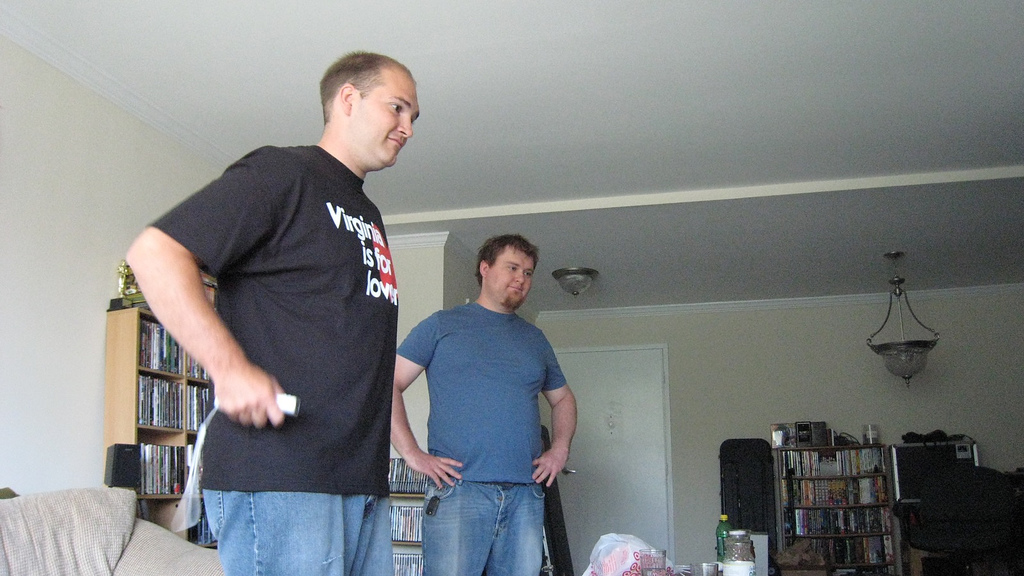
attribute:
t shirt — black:
[137, 146, 395, 502]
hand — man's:
[202, 355, 288, 425]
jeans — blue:
[421, 471, 552, 573]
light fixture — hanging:
[859, 244, 946, 390]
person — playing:
[130, 48, 425, 573]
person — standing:
[382, 229, 586, 572]